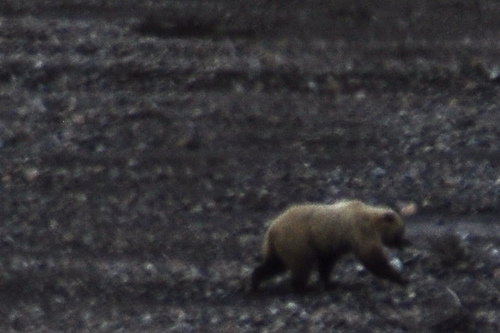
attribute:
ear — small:
[372, 210, 403, 225]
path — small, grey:
[11, 240, 498, 331]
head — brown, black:
[377, 204, 417, 252]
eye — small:
[393, 230, 402, 237]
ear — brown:
[372, 207, 395, 237]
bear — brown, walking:
[255, 189, 414, 289]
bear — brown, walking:
[241, 197, 413, 298]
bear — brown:
[238, 179, 413, 299]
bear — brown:
[245, 195, 414, 305]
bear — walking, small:
[235, 195, 414, 293]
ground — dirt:
[3, 3, 497, 330]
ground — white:
[8, 252, 314, 329]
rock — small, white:
[388, 255, 402, 273]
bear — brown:
[226, 155, 457, 314]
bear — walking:
[279, 205, 409, 280]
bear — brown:
[258, 195, 396, 300]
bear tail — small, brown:
[260, 228, 282, 261]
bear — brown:
[243, 190, 420, 298]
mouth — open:
[398, 244, 411, 258]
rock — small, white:
[145, 262, 153, 271]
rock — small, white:
[390, 253, 400, 269]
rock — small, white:
[147, 312, 153, 321]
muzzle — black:
[398, 233, 412, 246]